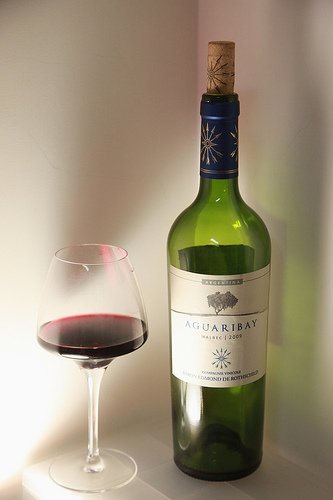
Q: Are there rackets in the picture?
A: No, there are no rackets.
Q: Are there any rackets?
A: No, there are no rackets.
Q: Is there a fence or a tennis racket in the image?
A: No, there are no rackets or fences.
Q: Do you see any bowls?
A: No, there are no bowls.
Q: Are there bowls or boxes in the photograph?
A: No, there are no bowls or boxes.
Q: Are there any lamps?
A: No, there are no lamps.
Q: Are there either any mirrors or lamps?
A: No, there are no lamps or mirrors.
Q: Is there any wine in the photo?
A: Yes, there is wine.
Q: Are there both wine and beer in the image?
A: No, there is wine but no beer.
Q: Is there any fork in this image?
A: No, there are no forks.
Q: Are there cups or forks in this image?
A: No, there are no forks or cups.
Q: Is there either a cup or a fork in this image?
A: No, there are no forks or cups.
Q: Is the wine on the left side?
A: Yes, the wine is on the left of the image.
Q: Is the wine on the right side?
A: No, the wine is on the left of the image.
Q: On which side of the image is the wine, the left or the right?
A: The wine is on the left of the image.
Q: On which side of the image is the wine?
A: The wine is on the left of the image.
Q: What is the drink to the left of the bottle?
A: The drink is wine.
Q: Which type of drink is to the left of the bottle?
A: The drink is wine.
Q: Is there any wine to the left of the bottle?
A: Yes, there is wine to the left of the bottle.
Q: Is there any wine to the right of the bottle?
A: No, the wine is to the left of the bottle.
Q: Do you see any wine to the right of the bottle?
A: No, the wine is to the left of the bottle.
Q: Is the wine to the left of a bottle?
A: Yes, the wine is to the left of a bottle.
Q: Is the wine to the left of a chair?
A: No, the wine is to the left of a bottle.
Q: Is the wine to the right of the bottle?
A: No, the wine is to the left of the bottle.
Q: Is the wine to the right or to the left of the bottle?
A: The wine is to the left of the bottle.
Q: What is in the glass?
A: The wine is in the glass.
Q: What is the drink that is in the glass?
A: The drink is wine.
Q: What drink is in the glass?
A: The drink is wine.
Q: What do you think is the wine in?
A: The wine is in the glass.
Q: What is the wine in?
A: The wine is in the glass.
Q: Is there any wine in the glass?
A: Yes, there is wine in the glass.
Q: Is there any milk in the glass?
A: No, there is wine in the glass.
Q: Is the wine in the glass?
A: Yes, the wine is in the glass.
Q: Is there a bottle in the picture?
A: Yes, there is a bottle.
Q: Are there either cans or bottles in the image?
A: Yes, there is a bottle.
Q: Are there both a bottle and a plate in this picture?
A: No, there is a bottle but no plates.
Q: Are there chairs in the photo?
A: No, there are no chairs.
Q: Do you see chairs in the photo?
A: No, there are no chairs.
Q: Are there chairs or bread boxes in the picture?
A: No, there are no chairs or bread boxes.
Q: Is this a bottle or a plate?
A: This is a bottle.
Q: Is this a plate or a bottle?
A: This is a bottle.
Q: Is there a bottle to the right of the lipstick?
A: Yes, there is a bottle to the right of the lipstick.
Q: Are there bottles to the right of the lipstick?
A: Yes, there is a bottle to the right of the lipstick.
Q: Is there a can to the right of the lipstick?
A: No, there is a bottle to the right of the lipstick.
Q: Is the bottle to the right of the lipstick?
A: Yes, the bottle is to the right of the lipstick.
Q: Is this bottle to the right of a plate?
A: No, the bottle is to the right of the lipstick.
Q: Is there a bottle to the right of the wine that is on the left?
A: Yes, there is a bottle to the right of the wine.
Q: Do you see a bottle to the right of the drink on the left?
A: Yes, there is a bottle to the right of the wine.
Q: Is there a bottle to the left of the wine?
A: No, the bottle is to the right of the wine.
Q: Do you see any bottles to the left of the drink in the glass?
A: No, the bottle is to the right of the wine.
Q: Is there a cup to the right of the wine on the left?
A: No, there is a bottle to the right of the wine.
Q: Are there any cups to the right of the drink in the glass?
A: No, there is a bottle to the right of the wine.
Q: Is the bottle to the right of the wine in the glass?
A: Yes, the bottle is to the right of the wine.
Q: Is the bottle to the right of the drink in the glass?
A: Yes, the bottle is to the right of the wine.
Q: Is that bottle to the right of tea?
A: No, the bottle is to the right of the wine.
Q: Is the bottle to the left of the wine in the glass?
A: No, the bottle is to the right of the wine.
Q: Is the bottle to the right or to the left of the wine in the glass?
A: The bottle is to the right of the wine.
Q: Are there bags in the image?
A: No, there are no bags.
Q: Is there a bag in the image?
A: No, there are no bags.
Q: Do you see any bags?
A: No, there are no bags.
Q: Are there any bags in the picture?
A: No, there are no bags.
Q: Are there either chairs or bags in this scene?
A: No, there are no bags or chairs.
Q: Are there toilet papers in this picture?
A: No, there are no toilet papers.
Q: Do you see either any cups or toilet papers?
A: No, there are no toilet papers or cups.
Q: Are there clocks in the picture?
A: No, there are no clocks.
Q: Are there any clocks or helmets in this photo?
A: No, there are no clocks or helmets.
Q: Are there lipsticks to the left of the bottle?
A: Yes, there is a lipstick to the left of the bottle.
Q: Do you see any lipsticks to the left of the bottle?
A: Yes, there is a lipstick to the left of the bottle.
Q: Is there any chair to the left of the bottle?
A: No, there is a lipstick to the left of the bottle.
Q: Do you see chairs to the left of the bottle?
A: No, there is a lipstick to the left of the bottle.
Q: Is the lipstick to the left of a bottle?
A: Yes, the lipstick is to the left of a bottle.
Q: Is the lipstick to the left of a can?
A: No, the lipstick is to the left of a bottle.